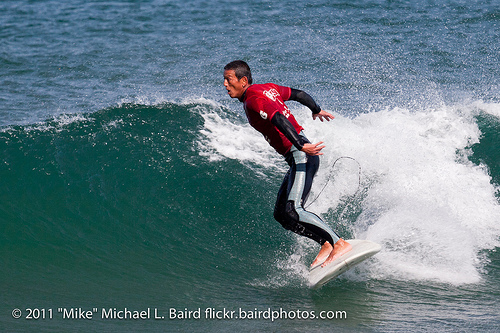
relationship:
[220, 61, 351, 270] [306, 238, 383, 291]
man on surfboard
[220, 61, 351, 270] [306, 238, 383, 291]
man riding surfboard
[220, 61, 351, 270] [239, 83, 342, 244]
man wearing wet suit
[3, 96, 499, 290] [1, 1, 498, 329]
wave in ocean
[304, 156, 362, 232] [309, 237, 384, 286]
cord attached to surf board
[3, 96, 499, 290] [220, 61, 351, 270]
wave behind man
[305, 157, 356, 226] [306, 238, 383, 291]
cord attached to surfboard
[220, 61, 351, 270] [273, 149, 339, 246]
man wearing lightweight pants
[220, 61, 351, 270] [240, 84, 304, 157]
man wearing red shirt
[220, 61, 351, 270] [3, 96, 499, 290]
man riding wave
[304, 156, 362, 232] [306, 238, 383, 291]
cord attached to surfboard